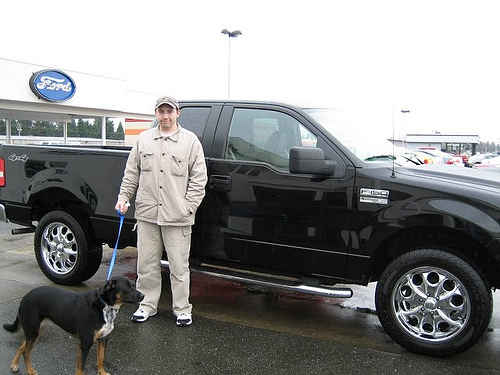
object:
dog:
[0, 274, 144, 375]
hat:
[154, 96, 180, 110]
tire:
[29, 213, 99, 286]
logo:
[29, 68, 75, 103]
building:
[0, 52, 494, 210]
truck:
[0, 98, 500, 356]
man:
[115, 97, 209, 328]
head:
[106, 276, 145, 306]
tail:
[1, 295, 29, 333]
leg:
[8, 319, 43, 366]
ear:
[105, 280, 116, 292]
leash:
[104, 212, 126, 283]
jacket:
[118, 125, 208, 229]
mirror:
[287, 144, 335, 178]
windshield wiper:
[362, 152, 420, 166]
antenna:
[389, 98, 398, 178]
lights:
[219, 27, 245, 39]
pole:
[226, 41, 231, 101]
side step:
[144, 243, 354, 300]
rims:
[373, 239, 493, 359]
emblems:
[357, 186, 391, 205]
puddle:
[327, 288, 376, 314]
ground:
[0, 251, 500, 375]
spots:
[104, 304, 120, 324]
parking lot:
[0, 224, 500, 375]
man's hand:
[114, 193, 131, 215]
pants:
[134, 222, 191, 314]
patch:
[97, 302, 121, 342]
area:
[94, 303, 119, 338]